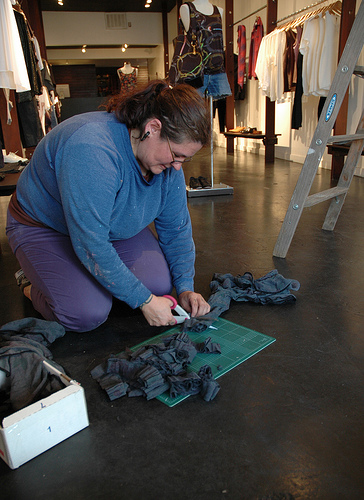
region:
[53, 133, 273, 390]
a woman is cutting material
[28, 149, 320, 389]
she is working on the floor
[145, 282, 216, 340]
she holding a pair of scissors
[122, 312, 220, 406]
the material is blue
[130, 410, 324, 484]
the floor is colored gray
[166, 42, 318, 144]
this is a clothing store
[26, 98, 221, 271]
this lady is wearing a blue shirt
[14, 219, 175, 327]
she has on blue pants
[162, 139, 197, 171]
the lady is wearing glasses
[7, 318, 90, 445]
a white box with material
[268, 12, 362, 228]
wooden step ladder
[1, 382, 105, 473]
white box on the floor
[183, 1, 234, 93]
clothes on display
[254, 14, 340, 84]
clothes hanging on a rack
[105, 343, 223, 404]
pieces of fabric in a pile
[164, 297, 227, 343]
woman cutting fabric pieces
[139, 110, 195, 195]
woman wearing glasses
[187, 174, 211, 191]
shoes by the mannequin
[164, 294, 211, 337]
white and pink scissors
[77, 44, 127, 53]
lights on the wall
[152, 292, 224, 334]
she is cutting the cloth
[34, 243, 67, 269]
the pants are purple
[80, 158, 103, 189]
the shirt is blue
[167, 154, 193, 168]
she is wearing glasses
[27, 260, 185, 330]
she is on her knees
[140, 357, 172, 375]
the material is gray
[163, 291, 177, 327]
the handles are pink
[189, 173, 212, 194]
the shoes are on the stand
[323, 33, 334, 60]
the shirt is white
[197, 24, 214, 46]
the shirt is multi color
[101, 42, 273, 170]
the head of a woman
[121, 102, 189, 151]
the ear of a woman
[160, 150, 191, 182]
the nose of a woman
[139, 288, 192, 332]
the hand of a woman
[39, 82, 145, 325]
the arm of a woman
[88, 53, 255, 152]
the hair of woman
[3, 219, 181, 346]
the leg of a woman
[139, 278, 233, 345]
scissors in a woman hand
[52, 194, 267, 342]
a woman on her knees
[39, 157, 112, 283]
the elbow of a woman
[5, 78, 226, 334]
woman cutting fabric with pink scissors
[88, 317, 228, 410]
pile of cut fabric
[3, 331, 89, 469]
clothing material in a white box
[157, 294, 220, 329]
pink scissors in a woman's hand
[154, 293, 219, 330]
scissors with pink handles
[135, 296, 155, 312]
tattoo on a woman's wrist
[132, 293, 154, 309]
wrist tattoo peeking from under a woman's sleeve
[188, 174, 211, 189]
pair of black shoes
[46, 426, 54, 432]
blue number one print on a box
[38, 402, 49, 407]
blue number seven print on a box